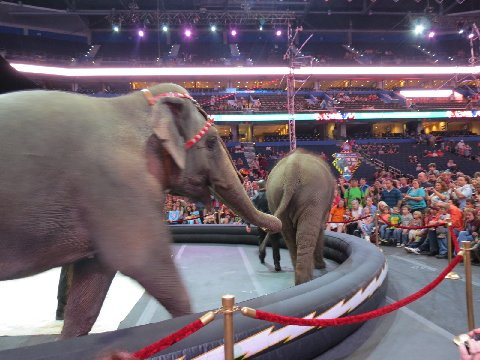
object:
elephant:
[0, 79, 284, 342]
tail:
[259, 162, 298, 260]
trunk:
[208, 135, 283, 235]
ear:
[151, 96, 191, 171]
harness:
[139, 87, 215, 152]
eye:
[205, 136, 217, 148]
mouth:
[204, 171, 219, 214]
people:
[424, 181, 449, 211]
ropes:
[241, 250, 465, 327]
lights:
[231, 30, 237, 36]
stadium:
[0, 0, 480, 360]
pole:
[458, 239, 476, 334]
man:
[245, 179, 283, 271]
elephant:
[257, 146, 338, 288]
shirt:
[329, 204, 346, 223]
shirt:
[405, 187, 427, 210]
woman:
[404, 179, 427, 213]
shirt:
[380, 187, 404, 208]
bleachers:
[0, 37, 479, 73]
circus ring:
[0, 222, 389, 359]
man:
[344, 178, 365, 208]